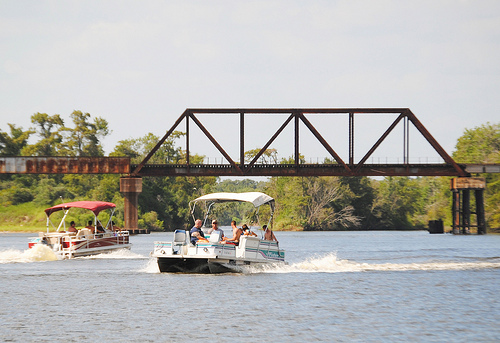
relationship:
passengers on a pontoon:
[191, 218, 279, 247] [152, 192, 287, 275]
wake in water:
[1, 243, 63, 265] [0, 225, 500, 342]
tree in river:
[304, 182, 366, 233] [0, 225, 500, 342]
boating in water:
[29, 192, 289, 276] [0, 225, 500, 342]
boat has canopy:
[28, 201, 134, 258] [189, 192, 276, 242]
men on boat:
[191, 218, 279, 247] [28, 201, 134, 258]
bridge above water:
[1, 107, 500, 234] [0, 225, 500, 342]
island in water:
[244, 148, 498, 233] [0, 225, 500, 342]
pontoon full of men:
[152, 192, 287, 275] [191, 218, 279, 247]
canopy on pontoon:
[44, 200, 118, 235] [28, 201, 134, 258]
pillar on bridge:
[120, 176, 150, 233] [1, 107, 500, 234]